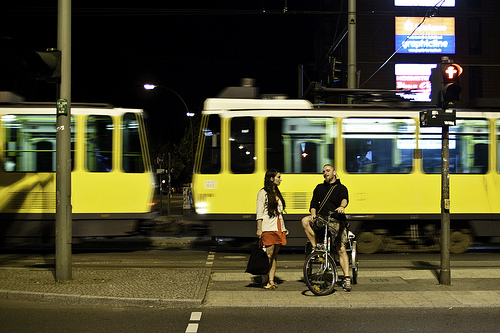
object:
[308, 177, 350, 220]
black jacket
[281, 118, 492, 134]
lights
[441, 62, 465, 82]
electric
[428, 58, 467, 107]
traffic signal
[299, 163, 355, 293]
man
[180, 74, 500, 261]
bus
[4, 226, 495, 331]
street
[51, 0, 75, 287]
pole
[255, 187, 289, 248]
dress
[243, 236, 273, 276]
backpack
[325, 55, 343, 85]
light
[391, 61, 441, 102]
ad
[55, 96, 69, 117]
sign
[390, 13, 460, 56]
advertisement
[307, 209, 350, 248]
shorts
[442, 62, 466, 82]
red light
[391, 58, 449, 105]
sign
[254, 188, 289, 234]
jacket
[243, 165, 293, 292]
girl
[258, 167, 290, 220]
hair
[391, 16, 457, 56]
sign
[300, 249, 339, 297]
tire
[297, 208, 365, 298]
bicycle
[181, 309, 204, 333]
line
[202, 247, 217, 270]
line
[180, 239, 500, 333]
crosswalk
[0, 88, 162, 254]
car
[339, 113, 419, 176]
window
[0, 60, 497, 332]
corner